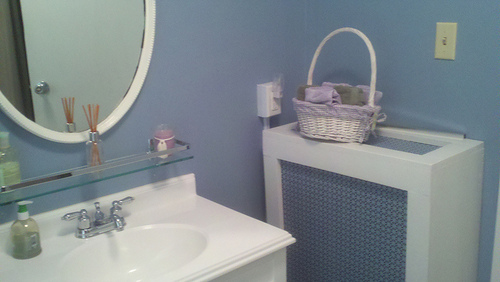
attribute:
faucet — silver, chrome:
[60, 192, 133, 237]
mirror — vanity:
[2, 0, 144, 131]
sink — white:
[56, 223, 207, 280]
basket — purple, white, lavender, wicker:
[293, 27, 385, 147]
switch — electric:
[433, 20, 459, 63]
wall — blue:
[307, 2, 497, 280]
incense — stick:
[81, 97, 103, 164]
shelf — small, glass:
[0, 151, 198, 212]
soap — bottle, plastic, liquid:
[7, 195, 44, 259]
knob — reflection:
[32, 78, 51, 96]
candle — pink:
[151, 124, 177, 161]